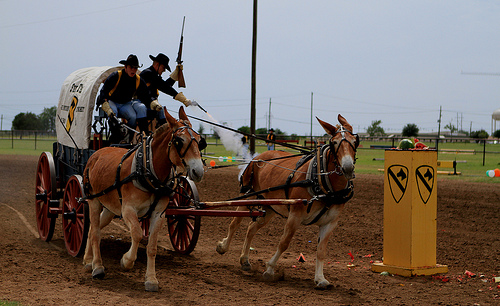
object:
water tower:
[487, 108, 499, 138]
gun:
[188, 98, 207, 113]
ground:
[441, 179, 499, 214]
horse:
[213, 114, 360, 289]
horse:
[81, 106, 204, 292]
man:
[143, 53, 194, 128]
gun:
[175, 15, 185, 87]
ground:
[445, 227, 500, 267]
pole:
[249, 0, 257, 159]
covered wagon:
[34, 65, 309, 260]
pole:
[371, 148, 450, 277]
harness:
[127, 133, 182, 203]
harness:
[306, 138, 353, 202]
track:
[0, 200, 42, 238]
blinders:
[174, 135, 209, 150]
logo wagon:
[46, 83, 86, 139]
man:
[97, 54, 161, 145]